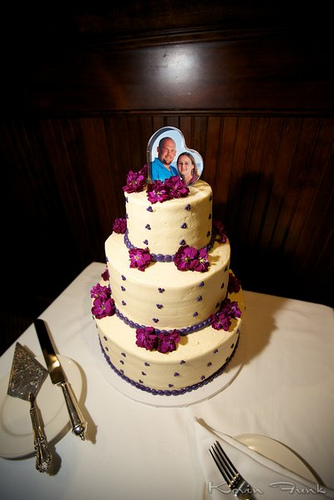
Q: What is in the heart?
A: A photo of a man and woman.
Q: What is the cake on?
A: Table.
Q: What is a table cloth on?
A: Table.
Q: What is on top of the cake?
A: Heartshape picture.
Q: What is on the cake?
A: Purple flowers.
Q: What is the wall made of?
A: Wood.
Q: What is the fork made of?
A: Metal.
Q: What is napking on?
A: Plate.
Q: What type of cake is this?
A: Wedding cake.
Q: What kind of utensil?
A: Silver.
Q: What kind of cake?
A: Wedding.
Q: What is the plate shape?
A: Round.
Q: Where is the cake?
A: Table.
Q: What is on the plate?
A: Fork.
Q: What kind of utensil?
A: Knife.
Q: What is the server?
A: Ornate.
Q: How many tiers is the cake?
A: 3.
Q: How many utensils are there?
A: 3.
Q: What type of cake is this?
A: Wedding cake.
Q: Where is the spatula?
A: On a plate.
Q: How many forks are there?
A: 1.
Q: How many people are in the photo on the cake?
A: 2.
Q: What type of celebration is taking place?
A: Wedding.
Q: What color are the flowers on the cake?
A: Purple.